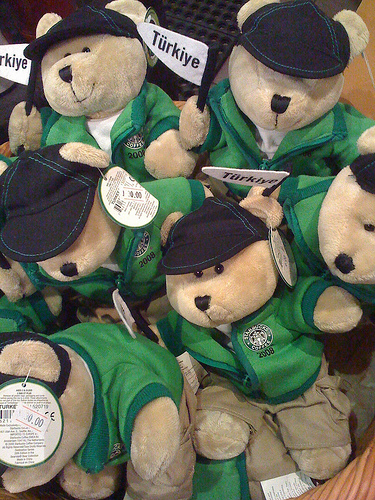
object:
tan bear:
[139, 196, 363, 480]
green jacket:
[154, 272, 338, 405]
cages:
[77, 0, 281, 120]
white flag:
[135, 11, 225, 90]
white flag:
[192, 143, 306, 196]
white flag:
[0, 41, 37, 89]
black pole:
[195, 39, 218, 116]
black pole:
[24, 56, 39, 113]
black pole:
[262, 169, 293, 200]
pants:
[195, 366, 353, 417]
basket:
[290, 441, 375, 499]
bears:
[0, 0, 375, 500]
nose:
[186, 291, 216, 314]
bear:
[149, 207, 369, 485]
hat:
[168, 200, 274, 280]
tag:
[267, 223, 299, 289]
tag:
[1, 375, 64, 470]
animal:
[155, 191, 365, 482]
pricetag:
[10, 398, 55, 431]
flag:
[136, 24, 213, 83]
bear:
[136, 4, 367, 167]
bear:
[0, 5, 145, 168]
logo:
[243, 319, 274, 354]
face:
[225, 35, 339, 130]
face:
[318, 172, 373, 283]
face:
[32, 26, 147, 113]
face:
[35, 189, 117, 285]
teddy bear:
[0, 143, 163, 312]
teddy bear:
[157, 193, 364, 480]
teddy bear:
[270, 115, 374, 303]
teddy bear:
[181, 1, 372, 177]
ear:
[240, 195, 283, 228]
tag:
[133, 17, 212, 86]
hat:
[158, 195, 269, 275]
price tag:
[0, 385, 68, 471]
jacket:
[200, 79, 368, 179]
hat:
[241, 9, 348, 79]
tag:
[87, 145, 155, 220]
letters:
[132, 23, 206, 83]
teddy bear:
[25, 0, 188, 177]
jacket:
[38, 103, 175, 177]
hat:
[23, 4, 139, 60]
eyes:
[212, 262, 227, 272]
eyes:
[189, 263, 205, 277]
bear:
[163, 199, 365, 337]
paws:
[175, 92, 211, 149]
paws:
[139, 136, 197, 176]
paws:
[7, 92, 43, 152]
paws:
[313, 286, 364, 334]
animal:
[179, 0, 375, 172]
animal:
[10, 0, 183, 162]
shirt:
[194, 130, 319, 211]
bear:
[140, 2, 374, 175]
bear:
[1, 142, 172, 306]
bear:
[277, 125, 373, 290]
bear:
[153, 188, 363, 486]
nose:
[268, 91, 294, 124]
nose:
[53, 60, 81, 89]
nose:
[329, 251, 360, 277]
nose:
[58, 260, 82, 278]